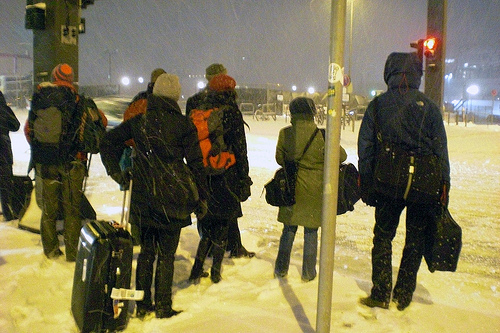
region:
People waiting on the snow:
[0, 31, 488, 332]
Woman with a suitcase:
[65, 66, 223, 332]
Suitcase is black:
[61, 204, 147, 331]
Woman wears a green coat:
[265, 78, 355, 287]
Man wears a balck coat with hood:
[351, 40, 471, 313]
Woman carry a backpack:
[185, 66, 264, 289]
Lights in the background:
[108, 59, 143, 88]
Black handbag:
[258, 147, 306, 219]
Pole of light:
[302, 4, 347, 332]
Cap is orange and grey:
[52, 61, 79, 84]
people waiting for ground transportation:
[20, 49, 467, 328]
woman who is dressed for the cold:
[95, 72, 208, 318]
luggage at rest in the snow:
[66, 161, 140, 331]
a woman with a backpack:
[184, 70, 251, 285]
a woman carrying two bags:
[260, 97, 359, 283]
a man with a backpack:
[22, 62, 105, 260]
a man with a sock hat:
[26, 58, 110, 266]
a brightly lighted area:
[2, 67, 489, 249]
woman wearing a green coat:
[265, 92, 357, 282]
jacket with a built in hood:
[357, 50, 453, 203]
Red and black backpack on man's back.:
[189, 106, 236, 177]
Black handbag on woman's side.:
[268, 166, 297, 211]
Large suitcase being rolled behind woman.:
[73, 217, 134, 332]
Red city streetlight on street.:
[418, 33, 439, 56]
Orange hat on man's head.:
[53, 63, 75, 88]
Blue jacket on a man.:
[358, 51, 453, 199]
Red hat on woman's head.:
[207, 75, 237, 89]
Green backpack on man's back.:
[30, 90, 70, 152]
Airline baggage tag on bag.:
[112, 289, 142, 299]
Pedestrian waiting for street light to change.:
[264, 96, 349, 283]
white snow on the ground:
[202, 285, 287, 316]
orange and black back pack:
[191, 104, 245, 173]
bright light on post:
[391, 23, 482, 75]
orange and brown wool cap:
[46, 64, 91, 89]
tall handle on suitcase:
[112, 173, 142, 227]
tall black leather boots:
[185, 232, 250, 294]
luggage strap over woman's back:
[278, 118, 346, 180]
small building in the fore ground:
[0, 43, 40, 103]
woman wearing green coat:
[257, 103, 322, 273]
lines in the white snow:
[254, 230, 273, 287]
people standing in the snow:
[24, 42, 496, 196]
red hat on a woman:
[205, 75, 235, 100]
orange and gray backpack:
[192, 104, 243, 194]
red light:
[408, 25, 445, 65]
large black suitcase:
[62, 200, 147, 328]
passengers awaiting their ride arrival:
[3, 37, 464, 272]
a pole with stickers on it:
[315, 14, 351, 304]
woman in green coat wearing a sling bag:
[266, 88, 344, 262]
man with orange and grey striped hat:
[19, 57, 106, 211]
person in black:
[112, 57, 242, 318]